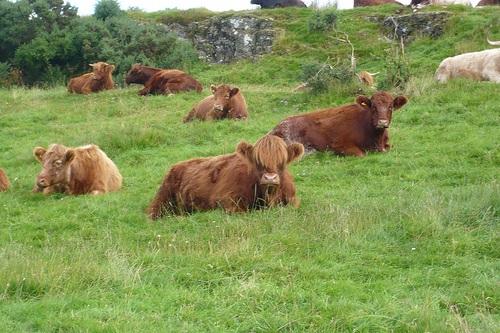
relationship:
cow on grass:
[147, 134, 304, 220] [0, 1, 499, 330]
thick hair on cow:
[250, 134, 289, 170] [147, 134, 304, 220]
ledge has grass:
[149, 1, 500, 69] [0, 1, 499, 330]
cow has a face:
[147, 134, 304, 220] [255, 154, 286, 190]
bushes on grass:
[1, 0, 212, 90] [0, 1, 499, 330]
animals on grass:
[0, 33, 500, 222] [0, 1, 499, 330]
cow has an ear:
[147, 134, 304, 220] [286, 143, 304, 164]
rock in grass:
[157, 13, 281, 66] [0, 1, 499, 330]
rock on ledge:
[157, 13, 281, 66] [149, 1, 500, 69]